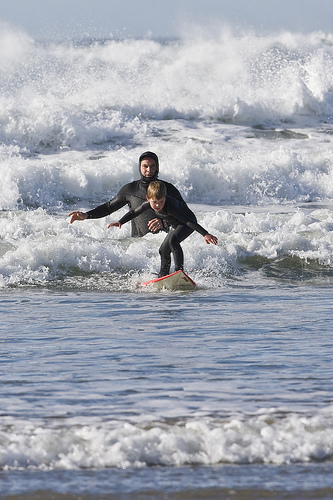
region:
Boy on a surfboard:
[110, 181, 222, 288]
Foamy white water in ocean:
[3, 418, 329, 473]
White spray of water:
[173, 9, 240, 46]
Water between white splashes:
[253, 123, 309, 142]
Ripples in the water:
[108, 345, 246, 392]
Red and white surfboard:
[146, 268, 196, 289]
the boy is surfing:
[114, 175, 211, 298]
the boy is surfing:
[117, 187, 198, 292]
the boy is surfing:
[112, 177, 203, 307]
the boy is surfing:
[117, 165, 193, 304]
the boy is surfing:
[117, 173, 191, 302]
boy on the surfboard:
[126, 175, 195, 274]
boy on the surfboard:
[117, 180, 182, 275]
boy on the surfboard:
[117, 179, 204, 269]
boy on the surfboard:
[112, 182, 206, 294]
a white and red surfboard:
[142, 268, 196, 293]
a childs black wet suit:
[118, 200, 207, 269]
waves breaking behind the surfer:
[0, 18, 332, 149]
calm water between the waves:
[0, 296, 332, 410]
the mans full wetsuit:
[84, 152, 145, 201]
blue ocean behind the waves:
[28, 31, 184, 47]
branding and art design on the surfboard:
[170, 275, 193, 291]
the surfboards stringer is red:
[172, 270, 182, 291]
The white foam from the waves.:
[5, 417, 173, 471]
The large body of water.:
[9, 304, 327, 495]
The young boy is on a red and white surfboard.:
[133, 271, 200, 295]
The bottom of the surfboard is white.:
[143, 274, 196, 292]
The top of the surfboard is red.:
[131, 272, 197, 292]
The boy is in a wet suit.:
[116, 203, 204, 276]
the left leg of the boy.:
[155, 229, 173, 275]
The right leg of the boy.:
[171, 224, 194, 269]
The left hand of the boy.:
[109, 203, 149, 224]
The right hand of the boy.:
[171, 213, 226, 250]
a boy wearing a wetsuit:
[138, 169, 247, 304]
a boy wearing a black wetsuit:
[127, 193, 214, 278]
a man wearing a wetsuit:
[94, 132, 244, 335]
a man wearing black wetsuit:
[100, 152, 172, 266]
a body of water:
[16, 277, 292, 487]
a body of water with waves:
[15, 196, 268, 487]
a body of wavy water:
[57, 208, 321, 393]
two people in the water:
[96, 154, 195, 305]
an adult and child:
[64, 92, 243, 316]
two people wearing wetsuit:
[100, 138, 247, 339]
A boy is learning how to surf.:
[105, 180, 219, 277]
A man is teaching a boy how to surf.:
[66, 149, 170, 235]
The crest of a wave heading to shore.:
[0, 411, 331, 470]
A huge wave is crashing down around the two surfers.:
[0, 30, 332, 292]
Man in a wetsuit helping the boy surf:
[67, 152, 182, 240]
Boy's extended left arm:
[176, 203, 217, 247]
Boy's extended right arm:
[107, 201, 149, 230]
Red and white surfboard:
[141, 264, 197, 293]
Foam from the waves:
[0, 419, 331, 468]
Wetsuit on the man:
[68, 148, 185, 238]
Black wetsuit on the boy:
[118, 202, 205, 276]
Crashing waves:
[0, 24, 331, 133]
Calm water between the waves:
[0, 290, 329, 415]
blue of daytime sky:
[1, 1, 331, 35]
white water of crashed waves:
[1, 28, 332, 279]